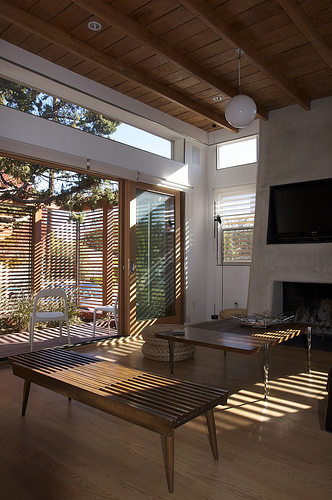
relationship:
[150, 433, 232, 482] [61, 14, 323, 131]
legs hanging from ceiling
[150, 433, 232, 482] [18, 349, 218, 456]
legs attached to bench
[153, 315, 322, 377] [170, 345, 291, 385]
table has legs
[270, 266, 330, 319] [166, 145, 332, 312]
fireplace by wall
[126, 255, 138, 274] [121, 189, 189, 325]
handle on door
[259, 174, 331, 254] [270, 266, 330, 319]
tv above fireplace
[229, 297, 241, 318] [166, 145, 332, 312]
socket on wall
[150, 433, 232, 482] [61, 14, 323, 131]
legs on ceiling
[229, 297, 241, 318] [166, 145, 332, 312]
socket attached to wall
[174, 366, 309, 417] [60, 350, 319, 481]
shadow on floor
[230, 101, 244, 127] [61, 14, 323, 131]
bulb hanging from ceiling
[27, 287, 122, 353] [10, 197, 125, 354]
chairs on patio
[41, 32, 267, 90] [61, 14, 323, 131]
beam in ceiling